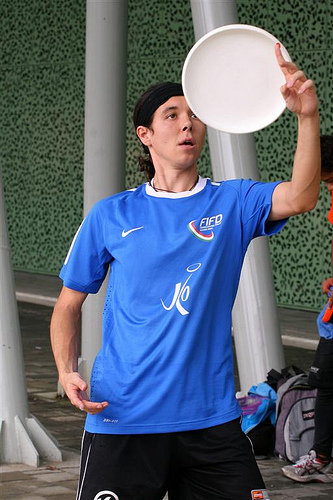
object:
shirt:
[58, 177, 286, 436]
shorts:
[72, 420, 267, 497]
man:
[48, 43, 321, 499]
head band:
[133, 83, 189, 130]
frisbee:
[181, 21, 293, 137]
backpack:
[275, 368, 320, 465]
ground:
[0, 299, 333, 500]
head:
[133, 81, 206, 170]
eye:
[167, 113, 177, 119]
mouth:
[178, 139, 197, 149]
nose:
[181, 116, 193, 132]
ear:
[135, 124, 154, 147]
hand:
[274, 44, 321, 116]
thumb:
[74, 377, 88, 391]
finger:
[275, 41, 289, 81]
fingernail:
[81, 405, 83, 409]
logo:
[121, 224, 144, 239]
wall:
[0, 0, 331, 316]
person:
[314, 132, 332, 484]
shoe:
[279, 448, 332, 483]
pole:
[57, 1, 127, 401]